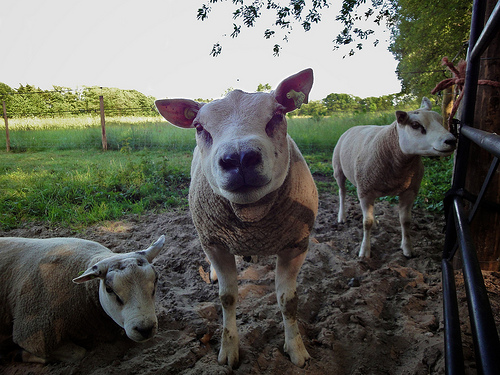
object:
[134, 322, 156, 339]
nose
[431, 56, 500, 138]
red rope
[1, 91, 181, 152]
fence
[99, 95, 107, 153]
post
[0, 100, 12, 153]
post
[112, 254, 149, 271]
hair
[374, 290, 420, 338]
ground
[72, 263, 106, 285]
ear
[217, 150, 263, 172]
nose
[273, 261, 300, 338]
leg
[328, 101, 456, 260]
animal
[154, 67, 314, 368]
animal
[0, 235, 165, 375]
animal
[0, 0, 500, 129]
trees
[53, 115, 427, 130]
grass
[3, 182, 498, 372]
sand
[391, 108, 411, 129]
ears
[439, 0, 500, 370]
fence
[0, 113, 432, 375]
field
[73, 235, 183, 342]
head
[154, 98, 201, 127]
ear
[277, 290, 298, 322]
mud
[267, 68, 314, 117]
ear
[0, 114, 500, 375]
shade